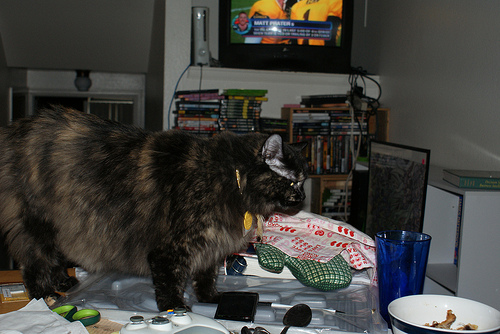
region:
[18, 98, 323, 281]
fat cat on the table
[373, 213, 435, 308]
blue glass on the table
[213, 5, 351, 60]
tv on the shelf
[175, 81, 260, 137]
dvds on a shelf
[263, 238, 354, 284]
oven mitt on the counter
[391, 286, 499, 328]
bowl of food on the table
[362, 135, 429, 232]
poster leaning against the shelf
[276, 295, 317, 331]
spoon laying on the table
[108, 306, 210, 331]
game controller on the table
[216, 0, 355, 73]
the tv on the shelf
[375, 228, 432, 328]
the blue cup on the table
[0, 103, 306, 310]
the cat standing on the table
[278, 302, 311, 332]
the spoon on the table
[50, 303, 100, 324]
the handle for a pair of scissors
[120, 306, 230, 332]
the xbox controller on the table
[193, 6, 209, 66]
the xbox on the shelf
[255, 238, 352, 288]
the green and white oven mitt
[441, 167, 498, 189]
the book on the white shelf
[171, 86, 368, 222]
the stacked video games under the tv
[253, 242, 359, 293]
green oven mitt on the table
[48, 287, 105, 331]
scissors under the paper on the table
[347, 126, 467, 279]
poster against the wall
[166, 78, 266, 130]
dvds on a shelf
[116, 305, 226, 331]
game controller on the table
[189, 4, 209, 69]
game console by the tv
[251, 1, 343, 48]
the tv is on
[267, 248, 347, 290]
the mitts are green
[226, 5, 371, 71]
tv on the shelf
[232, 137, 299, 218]
face of the cat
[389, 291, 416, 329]
bowl on the right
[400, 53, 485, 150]
the wall is cream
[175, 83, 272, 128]
stacks of books and dvds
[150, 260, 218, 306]
front paws of cat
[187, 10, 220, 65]
system next to television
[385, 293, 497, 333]
bowl with food in it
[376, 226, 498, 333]
blue glass beside bowl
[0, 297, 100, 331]
top of a pair of scissors beneath a piece of paper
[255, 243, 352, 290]
section of a green oven mitt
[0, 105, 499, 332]
adult cat looking towards bowl of food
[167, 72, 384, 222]
DVDs arranged near a wall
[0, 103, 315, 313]
cat's long fur is black and brown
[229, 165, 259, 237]
yellow tag hung from cat's neck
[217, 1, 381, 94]
lower section of a television on a shelf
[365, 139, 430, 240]
artwork with a thin black frame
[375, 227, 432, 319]
a dark blue glass on the table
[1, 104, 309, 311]
a mostly dark gray fluffy cat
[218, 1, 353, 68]
A black framed television.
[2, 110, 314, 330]
A fat cat.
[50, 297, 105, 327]
Green scissor handles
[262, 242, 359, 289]
A green oven mit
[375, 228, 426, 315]
A blue cup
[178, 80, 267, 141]
A stack of game and DVD cases.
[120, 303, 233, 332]
A white XBOX 360 controller.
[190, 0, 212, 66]
A white xbox 360 game console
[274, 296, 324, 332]
A silver spoon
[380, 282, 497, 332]
A bowl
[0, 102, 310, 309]
the cat is very fluffy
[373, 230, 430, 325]
the cup is cobalt blue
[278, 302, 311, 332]
the spoon is large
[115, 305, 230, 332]
the xbox controller is white